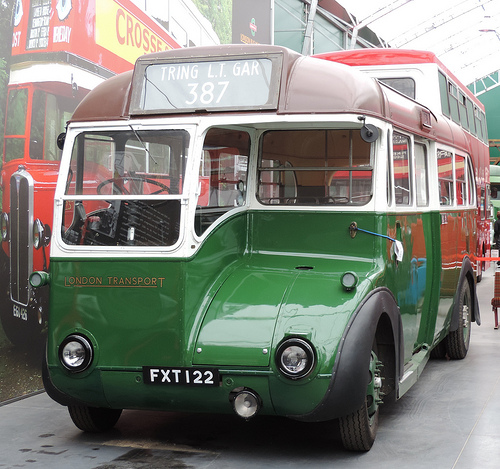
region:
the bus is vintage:
[62, 31, 499, 454]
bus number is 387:
[144, 45, 256, 133]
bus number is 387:
[118, 55, 306, 186]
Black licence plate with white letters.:
[140, 368, 223, 388]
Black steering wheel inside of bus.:
[93, 173, 176, 208]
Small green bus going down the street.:
[31, 49, 480, 451]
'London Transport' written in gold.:
[59, 274, 169, 290]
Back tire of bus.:
[439, 270, 475, 365]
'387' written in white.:
[180, 81, 229, 106]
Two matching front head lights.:
[55, 328, 314, 373]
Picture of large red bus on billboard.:
[0, 24, 199, 353]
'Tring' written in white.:
[155, 63, 198, 82]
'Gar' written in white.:
[232, 59, 263, 76]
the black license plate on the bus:
[142, 365, 219, 385]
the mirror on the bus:
[358, 112, 377, 141]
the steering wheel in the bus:
[96, 175, 172, 207]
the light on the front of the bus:
[57, 335, 90, 370]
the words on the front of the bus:
[62, 274, 165, 288]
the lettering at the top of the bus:
[159, 60, 259, 80]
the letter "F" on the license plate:
[148, 368, 158, 383]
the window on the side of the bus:
[391, 133, 411, 206]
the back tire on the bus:
[442, 275, 469, 360]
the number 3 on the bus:
[185, 83, 195, 103]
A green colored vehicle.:
[26, 42, 491, 454]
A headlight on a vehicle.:
[271, 334, 319, 385]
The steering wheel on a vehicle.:
[88, 173, 172, 212]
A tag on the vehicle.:
[143, 361, 220, 388]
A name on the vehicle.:
[55, 273, 167, 291]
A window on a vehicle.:
[389, 125, 416, 206]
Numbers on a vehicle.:
[179, 78, 231, 107]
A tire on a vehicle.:
[435, 273, 472, 361]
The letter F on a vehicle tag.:
[146, 365, 161, 382]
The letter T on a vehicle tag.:
[168, 365, 183, 382]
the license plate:
[141, 366, 221, 393]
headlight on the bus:
[276, 347, 308, 374]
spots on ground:
[115, 448, 179, 466]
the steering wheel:
[112, 167, 137, 187]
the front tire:
[345, 420, 374, 449]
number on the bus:
[179, 83, 231, 107]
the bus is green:
[226, 270, 301, 322]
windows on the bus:
[437, 149, 472, 203]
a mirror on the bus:
[30, 220, 47, 244]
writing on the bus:
[57, 273, 164, 300]